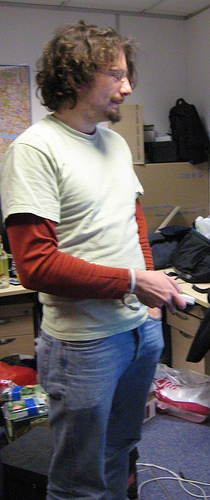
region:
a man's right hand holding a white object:
[136, 268, 195, 313]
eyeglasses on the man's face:
[100, 69, 129, 81]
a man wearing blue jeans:
[0, 22, 195, 496]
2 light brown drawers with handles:
[0, 315, 33, 360]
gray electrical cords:
[135, 459, 207, 495]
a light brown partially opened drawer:
[162, 306, 201, 336]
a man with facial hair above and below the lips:
[104, 96, 126, 123]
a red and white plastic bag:
[156, 364, 209, 414]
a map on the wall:
[0, 63, 31, 153]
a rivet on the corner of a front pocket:
[60, 339, 67, 346]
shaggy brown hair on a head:
[52, 24, 102, 63]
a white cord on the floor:
[163, 462, 200, 495]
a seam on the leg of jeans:
[59, 366, 70, 407]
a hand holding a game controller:
[139, 269, 181, 309]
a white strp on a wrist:
[127, 269, 136, 294]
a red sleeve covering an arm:
[15, 219, 42, 295]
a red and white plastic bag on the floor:
[167, 369, 209, 418]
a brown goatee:
[105, 106, 122, 121]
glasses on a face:
[110, 65, 131, 80]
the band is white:
[123, 267, 144, 294]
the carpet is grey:
[160, 429, 203, 472]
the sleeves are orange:
[22, 233, 140, 296]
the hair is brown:
[53, 29, 107, 100]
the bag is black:
[175, 226, 209, 282]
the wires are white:
[150, 459, 191, 498]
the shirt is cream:
[34, 132, 153, 325]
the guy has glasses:
[51, 32, 164, 269]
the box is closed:
[13, 441, 144, 495]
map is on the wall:
[4, 60, 35, 129]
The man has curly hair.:
[46, 36, 105, 98]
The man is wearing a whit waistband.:
[119, 259, 135, 293]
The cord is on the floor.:
[144, 452, 202, 495]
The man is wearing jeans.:
[50, 333, 178, 426]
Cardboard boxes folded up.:
[150, 168, 197, 208]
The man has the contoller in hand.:
[151, 278, 197, 311]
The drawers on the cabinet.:
[5, 299, 37, 372]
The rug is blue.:
[164, 420, 202, 465]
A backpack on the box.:
[156, 97, 201, 166]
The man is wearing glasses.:
[105, 63, 136, 83]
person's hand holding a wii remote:
[124, 266, 199, 316]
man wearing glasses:
[101, 66, 131, 84]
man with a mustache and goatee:
[104, 93, 124, 122]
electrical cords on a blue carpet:
[136, 460, 208, 497]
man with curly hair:
[36, 19, 130, 121]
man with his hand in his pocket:
[141, 302, 165, 357]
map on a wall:
[0, 62, 32, 160]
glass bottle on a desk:
[0, 236, 10, 290]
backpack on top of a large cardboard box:
[166, 95, 208, 162]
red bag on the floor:
[0, 357, 36, 387]